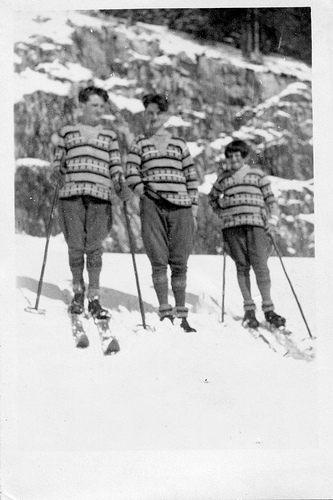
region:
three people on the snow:
[43, 79, 299, 330]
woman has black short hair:
[204, 133, 292, 335]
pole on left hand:
[255, 209, 329, 347]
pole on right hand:
[215, 217, 234, 330]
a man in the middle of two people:
[121, 88, 207, 339]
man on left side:
[39, 79, 127, 327]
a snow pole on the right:
[111, 167, 155, 334]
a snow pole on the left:
[32, 161, 64, 314]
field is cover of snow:
[1, 243, 329, 493]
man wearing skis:
[204, 132, 321, 369]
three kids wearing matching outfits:
[36, 82, 297, 356]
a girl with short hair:
[205, 131, 280, 327]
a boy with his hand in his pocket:
[113, 82, 196, 335]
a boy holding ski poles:
[26, 81, 133, 314]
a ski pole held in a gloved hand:
[112, 171, 151, 332]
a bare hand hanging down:
[185, 207, 201, 239]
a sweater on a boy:
[50, 117, 125, 200]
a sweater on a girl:
[203, 159, 283, 232]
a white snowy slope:
[13, 250, 317, 477]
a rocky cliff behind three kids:
[13, 28, 314, 251]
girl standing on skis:
[210, 137, 307, 339]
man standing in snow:
[133, 94, 198, 337]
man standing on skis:
[51, 84, 124, 324]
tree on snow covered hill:
[211, 9, 291, 64]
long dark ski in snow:
[64, 292, 90, 352]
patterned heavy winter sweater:
[212, 169, 283, 229]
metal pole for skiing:
[115, 175, 151, 331]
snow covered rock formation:
[16, 14, 312, 254]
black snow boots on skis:
[241, 302, 288, 325]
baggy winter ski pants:
[139, 192, 197, 312]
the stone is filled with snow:
[128, 39, 197, 97]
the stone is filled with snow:
[165, 42, 214, 107]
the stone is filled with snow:
[168, 56, 239, 124]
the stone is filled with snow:
[183, 42, 224, 97]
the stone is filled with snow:
[135, 62, 201, 178]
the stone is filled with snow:
[106, 64, 180, 128]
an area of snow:
[149, 337, 231, 356]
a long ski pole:
[122, 222, 141, 283]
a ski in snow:
[97, 323, 118, 352]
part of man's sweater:
[74, 155, 106, 174]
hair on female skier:
[228, 139, 247, 148]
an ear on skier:
[77, 103, 85, 111]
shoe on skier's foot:
[265, 311, 282, 324]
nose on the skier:
[152, 114, 161, 119]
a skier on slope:
[207, 137, 307, 348]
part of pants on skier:
[172, 215, 186, 273]